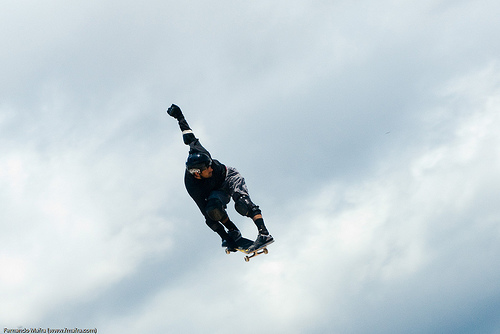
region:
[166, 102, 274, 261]
Skateboarder jumping in air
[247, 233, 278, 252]
wearing black shoes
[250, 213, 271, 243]
mans socks are black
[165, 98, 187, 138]
wearing black gloves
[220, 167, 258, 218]
man wearing grey pants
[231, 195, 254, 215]
black knee pad on man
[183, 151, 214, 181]
black protective helmet on head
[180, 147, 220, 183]
Man has facial hair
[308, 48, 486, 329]
very cloudy dark sky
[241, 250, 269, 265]
wheels are light colored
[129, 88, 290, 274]
person on a skateboard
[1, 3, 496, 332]
sky covered in gray and white clouds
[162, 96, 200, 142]
arm extended in the air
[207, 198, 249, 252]
arm on the skateboard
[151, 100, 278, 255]
person bent over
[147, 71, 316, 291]
person in the air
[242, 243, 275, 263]
two front wheels on the bottom of the board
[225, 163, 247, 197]
white on the side of the pants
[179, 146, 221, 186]
black helmet on the head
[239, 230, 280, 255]
foot firmly planted on the board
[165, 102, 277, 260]
A man on a skateboard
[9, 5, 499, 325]
A cloud covered sky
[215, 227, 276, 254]
Black sneakers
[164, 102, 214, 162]
An arm raised in the air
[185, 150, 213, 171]
A black helmet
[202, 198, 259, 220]
Two knees covered by kneepads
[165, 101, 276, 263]
A man taking a jump on a skateboard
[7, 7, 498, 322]
A man in black and grey against a cloud covered sky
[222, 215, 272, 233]
Black socks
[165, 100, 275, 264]
A man in a black shirt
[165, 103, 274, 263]
man in front of sky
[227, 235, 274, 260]
skateboard under man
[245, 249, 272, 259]
trucks under skateboard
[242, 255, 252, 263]
small wheels under skateboard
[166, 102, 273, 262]
man in skateboard is jumping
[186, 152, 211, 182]
man wearing a black helmet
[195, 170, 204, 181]
black chin strap under helmet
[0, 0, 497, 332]
blue sky behind man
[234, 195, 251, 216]
man wearing black knee pads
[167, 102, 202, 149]
arm is out stretched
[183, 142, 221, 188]
Person wearing black helmet.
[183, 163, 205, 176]
White writing on side of helmet.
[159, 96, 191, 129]
Person wearing black glove.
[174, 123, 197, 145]
Person wearing black elbow pad.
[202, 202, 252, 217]
Person wearing black knee pads.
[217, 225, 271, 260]
Person wearing black shoes.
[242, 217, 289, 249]
Person wearing black socks.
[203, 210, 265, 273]
Person standing on skateboard.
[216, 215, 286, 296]
Top of skateboard is black.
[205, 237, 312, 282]
Light colored wheels on skateboard.